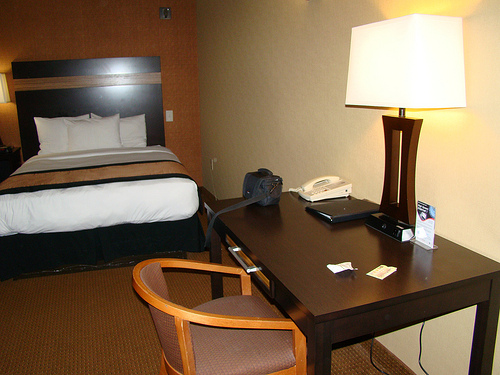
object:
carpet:
[0, 211, 416, 374]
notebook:
[366, 264, 398, 280]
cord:
[417, 321, 435, 374]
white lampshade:
[345, 13, 467, 108]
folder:
[305, 199, 380, 224]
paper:
[326, 261, 359, 274]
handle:
[228, 246, 261, 273]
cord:
[203, 192, 271, 249]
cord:
[370, 338, 389, 375]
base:
[376, 107, 425, 225]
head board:
[10, 55, 165, 162]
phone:
[289, 175, 353, 202]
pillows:
[33, 112, 147, 155]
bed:
[0, 0, 207, 280]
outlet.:
[208, 155, 217, 163]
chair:
[131, 258, 307, 374]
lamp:
[0, 72, 11, 105]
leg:
[467, 302, 499, 374]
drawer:
[220, 233, 276, 299]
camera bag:
[202, 168, 282, 248]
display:
[344, 13, 467, 232]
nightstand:
[204, 191, 500, 374]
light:
[98, 60, 136, 95]